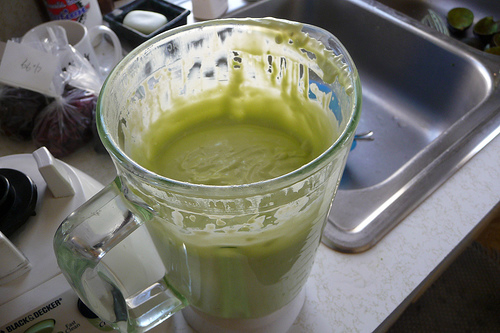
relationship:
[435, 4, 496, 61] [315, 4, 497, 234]
avocado in sink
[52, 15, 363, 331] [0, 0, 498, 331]
pitcher on counter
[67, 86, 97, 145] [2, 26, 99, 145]
items in bags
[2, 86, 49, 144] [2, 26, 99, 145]
items in bags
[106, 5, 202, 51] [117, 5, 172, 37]
container holding soap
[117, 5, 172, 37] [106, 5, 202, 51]
soap in container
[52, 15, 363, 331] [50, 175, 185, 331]
pitcher has handle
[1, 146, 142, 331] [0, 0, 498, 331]
blender base on counter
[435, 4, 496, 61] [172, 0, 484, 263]
avocado in sink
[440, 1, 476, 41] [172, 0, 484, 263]
avocado skin in sink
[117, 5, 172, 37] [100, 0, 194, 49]
soap in dish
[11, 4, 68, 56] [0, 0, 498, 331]
mug on counter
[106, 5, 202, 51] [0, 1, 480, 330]
container on counter top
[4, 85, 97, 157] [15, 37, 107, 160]
food in plastic bag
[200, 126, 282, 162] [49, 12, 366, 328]
avocado inside blender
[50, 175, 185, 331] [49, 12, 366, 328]
handle of blender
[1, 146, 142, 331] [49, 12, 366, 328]
blender base sitting next to blender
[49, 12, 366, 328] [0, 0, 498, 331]
blender sitting on top of counter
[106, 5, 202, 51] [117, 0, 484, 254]
container sitting on top of sink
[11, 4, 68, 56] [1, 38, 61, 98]
mug sitting behind tag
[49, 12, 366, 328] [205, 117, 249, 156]
blender containing paste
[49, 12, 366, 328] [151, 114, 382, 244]
blender containing cream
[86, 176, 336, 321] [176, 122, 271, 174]
blender containing cream